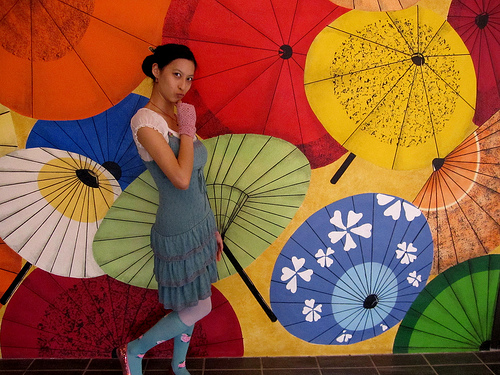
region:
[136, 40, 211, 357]
a lady posing to take photos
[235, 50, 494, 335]
a background colours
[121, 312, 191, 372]
a pair of socks with shoes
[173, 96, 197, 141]
a lady is using pink colour gloves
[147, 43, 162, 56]
a clip in the lady's head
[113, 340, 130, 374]
a brown colour shoe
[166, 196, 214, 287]
blue colour frock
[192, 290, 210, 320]
knee of the lady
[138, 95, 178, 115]
neck of the lady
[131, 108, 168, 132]
white colour t-shirt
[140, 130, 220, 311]
a woman with a blue dress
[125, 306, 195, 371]
a woman with blue and pink socks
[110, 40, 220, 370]
a woman facing to the right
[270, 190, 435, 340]
a blue and white umbrella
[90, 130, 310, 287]
green and black umbrella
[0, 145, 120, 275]
white and gold umbrella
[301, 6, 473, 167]
gold and black umbrella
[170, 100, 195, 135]
pink glove on woman right hand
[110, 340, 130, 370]
a woman wearing brown and black shoes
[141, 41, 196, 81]
a woman with black hair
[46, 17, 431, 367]
A woman is standing in a room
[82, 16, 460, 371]
A woman is standing in front of a painting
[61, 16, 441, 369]
Painted umbrellas are behind a woman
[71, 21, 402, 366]
A woman is smiling for someone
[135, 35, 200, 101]
A person has dark hair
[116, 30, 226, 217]
A person is wearing a glove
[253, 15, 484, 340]
Umbrellas painted on a wall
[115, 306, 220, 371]
Socks are on somebody's feet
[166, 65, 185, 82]
The eye of a person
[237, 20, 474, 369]
Colorful umbrellas are on a wall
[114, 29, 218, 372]
this is a lady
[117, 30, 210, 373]
the lady is standing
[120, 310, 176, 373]
the leg is lifted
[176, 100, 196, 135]
this is a glove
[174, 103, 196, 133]
the glove is pi k in color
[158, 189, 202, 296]
the dress is blue in color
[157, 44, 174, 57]
this is the hair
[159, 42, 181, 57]
the hair is black in color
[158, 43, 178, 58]
the hair is long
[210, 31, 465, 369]
the wall is painted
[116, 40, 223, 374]
the woman standing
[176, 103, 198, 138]
the glove on the woman's hand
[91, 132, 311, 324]
the green umbrella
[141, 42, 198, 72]
the hair on the woman's head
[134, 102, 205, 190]
the woman's right arm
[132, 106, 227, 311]
the dress on the woman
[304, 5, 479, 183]
the yellow umbrella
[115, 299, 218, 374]
the woman's leg from the knees down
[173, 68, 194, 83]
the woman's eyes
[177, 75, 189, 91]
the nose on the woman's face